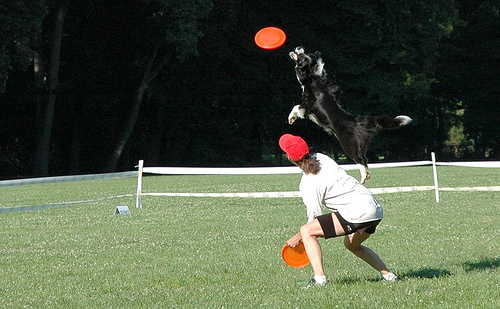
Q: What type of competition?
A: Frisbee.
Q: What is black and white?
A: Dog.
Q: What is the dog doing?
A: Jumping.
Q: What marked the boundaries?
A: Markers.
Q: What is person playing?
A: Frisbee.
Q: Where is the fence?
A: Behind person.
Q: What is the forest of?
A: Trees.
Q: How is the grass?
A: Lush.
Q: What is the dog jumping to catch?
A: A frisbee.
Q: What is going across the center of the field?
A: A fence.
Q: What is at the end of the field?
A: Trees.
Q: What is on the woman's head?
A: A red cap.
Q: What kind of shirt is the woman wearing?
A: A white t-shirt.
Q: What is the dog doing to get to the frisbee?
A: Jumping.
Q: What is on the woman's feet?
A: White shoes.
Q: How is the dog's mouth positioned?
A: It's open.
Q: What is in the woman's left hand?
A: Frisbee.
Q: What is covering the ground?
A: Green grass.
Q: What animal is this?
A: Dog.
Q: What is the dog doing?
A: Jumping after frisbee.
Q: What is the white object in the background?
A: Fence.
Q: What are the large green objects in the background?
A: Trees.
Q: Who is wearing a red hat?
A: A woman.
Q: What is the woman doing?
A: Preparing to throw frisbee.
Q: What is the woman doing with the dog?
A: Playing catch.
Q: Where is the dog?
A: In the air.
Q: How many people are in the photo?
A: One.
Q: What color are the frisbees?
A: Orange.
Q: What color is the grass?
A: Green.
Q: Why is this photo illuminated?
A: Sunlight.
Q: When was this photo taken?
A: During the day.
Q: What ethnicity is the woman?
A: Caucasian.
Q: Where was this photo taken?
A: A park.